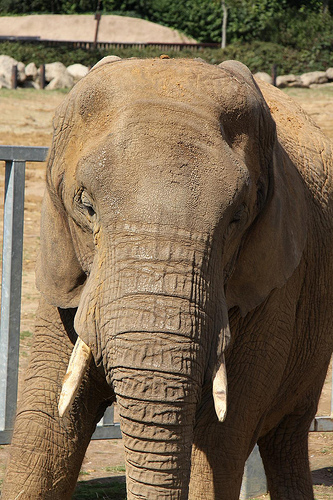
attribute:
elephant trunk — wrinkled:
[83, 177, 246, 496]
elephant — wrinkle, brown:
[36, 65, 323, 498]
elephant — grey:
[54, 53, 285, 467]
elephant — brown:
[49, 55, 304, 496]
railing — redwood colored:
[5, 38, 225, 58]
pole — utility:
[92, 19, 100, 54]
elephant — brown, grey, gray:
[0, 55, 331, 498]